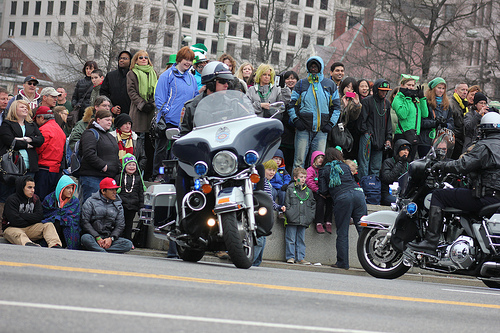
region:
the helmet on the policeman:
[201, 59, 236, 83]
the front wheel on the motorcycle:
[218, 213, 256, 268]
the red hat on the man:
[99, 176, 120, 188]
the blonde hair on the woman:
[5, 100, 34, 125]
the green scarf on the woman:
[130, 61, 157, 98]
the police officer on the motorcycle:
[403, 111, 498, 253]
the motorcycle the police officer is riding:
[160, 87, 279, 268]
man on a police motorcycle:
[173, 60, 285, 267]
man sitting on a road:
[79, 174, 134, 253]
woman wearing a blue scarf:
[316, 145, 373, 267]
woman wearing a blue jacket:
[148, 44, 198, 181]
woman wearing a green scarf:
[120, 45, 157, 168]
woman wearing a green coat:
[390, 73, 430, 133]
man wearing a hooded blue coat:
[285, 54, 342, 174]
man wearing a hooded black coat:
[99, 49, 131, 117]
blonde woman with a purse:
[1, 98, 42, 198]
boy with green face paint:
[280, 167, 315, 266]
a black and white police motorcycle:
[176, 86, 286, 267]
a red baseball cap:
[98, 176, 118, 189]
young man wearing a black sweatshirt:
[6, 173, 43, 227]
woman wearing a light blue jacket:
[154, 60, 199, 128]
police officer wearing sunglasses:
[213, 77, 232, 85]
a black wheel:
[354, 223, 413, 280]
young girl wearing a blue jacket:
[392, 88, 428, 134]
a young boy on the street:
[283, 167, 312, 267]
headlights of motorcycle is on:
[206, 206, 268, 227]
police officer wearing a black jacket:
[433, 130, 499, 201]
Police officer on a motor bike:
[163, 56, 298, 276]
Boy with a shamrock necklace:
[281, 165, 322, 269]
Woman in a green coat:
[386, 70, 432, 169]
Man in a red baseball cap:
[79, 173, 141, 258]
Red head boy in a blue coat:
[151, 42, 206, 163]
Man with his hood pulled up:
[284, 50, 341, 176]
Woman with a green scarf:
[121, 43, 162, 150]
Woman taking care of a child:
[305, 142, 376, 281]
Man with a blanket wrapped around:
[37, 166, 94, 253]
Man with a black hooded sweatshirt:
[3, 170, 67, 258]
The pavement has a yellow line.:
[41, 253, 126, 289]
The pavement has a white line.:
[31, 287, 128, 327]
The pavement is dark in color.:
[49, 272, 99, 307]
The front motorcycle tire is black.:
[217, 213, 260, 270]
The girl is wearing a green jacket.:
[389, 91, 424, 139]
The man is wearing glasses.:
[303, 58, 321, 75]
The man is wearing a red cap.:
[96, 177, 124, 200]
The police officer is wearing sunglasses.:
[196, 61, 236, 94]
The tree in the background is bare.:
[234, 0, 292, 61]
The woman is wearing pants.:
[326, 194, 373, 271]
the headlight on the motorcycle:
[213, 151, 238, 175]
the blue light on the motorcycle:
[192, 162, 208, 175]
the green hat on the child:
[118, 154, 146, 196]